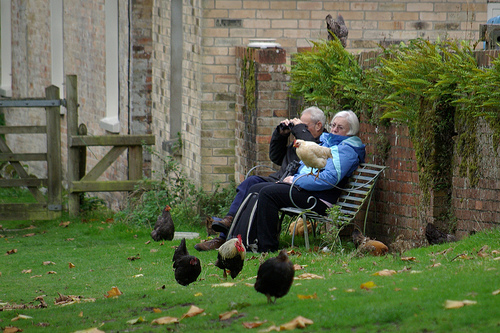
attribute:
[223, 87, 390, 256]
people — sitting, bench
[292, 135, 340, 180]
rooster — white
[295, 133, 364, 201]
coat — big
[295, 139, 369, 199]
coat — blue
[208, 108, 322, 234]
man — old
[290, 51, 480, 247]
wall — red, brick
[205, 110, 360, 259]
couple — old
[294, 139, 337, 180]
chicken — yellow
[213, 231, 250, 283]
rooster — black, white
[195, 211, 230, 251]
shoes — brown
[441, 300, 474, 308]
leaf — brown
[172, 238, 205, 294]
bird — large, black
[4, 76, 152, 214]
fence — wooden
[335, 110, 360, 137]
hair — gray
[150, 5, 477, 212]
building — brick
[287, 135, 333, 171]
bird — large, white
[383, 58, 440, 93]
leaves — green, tree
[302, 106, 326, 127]
hair — man's, short cut, gray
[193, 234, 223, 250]
shoe — brown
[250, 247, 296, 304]
chicken — fat, black, female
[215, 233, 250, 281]
chicken — female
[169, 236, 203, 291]
chicken — female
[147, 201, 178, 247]
chicken — female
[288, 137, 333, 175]
chicken — light brown, yellow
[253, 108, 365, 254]
woman — old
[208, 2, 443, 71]
wall — brick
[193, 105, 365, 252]
couple — older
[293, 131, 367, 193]
jacket — blue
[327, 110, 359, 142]
hair — gray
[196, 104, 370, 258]
people — old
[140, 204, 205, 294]
fowls — black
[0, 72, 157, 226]
fence — brown, wooden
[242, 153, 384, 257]
bench — green , metal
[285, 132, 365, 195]
jacket — light blue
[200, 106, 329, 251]
man — old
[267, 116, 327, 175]
jacket — black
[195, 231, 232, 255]
shoes — brown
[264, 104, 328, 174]
man — old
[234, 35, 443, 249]
wall — bricked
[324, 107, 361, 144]
hair — short, grey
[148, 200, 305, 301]
chickens — some, walking around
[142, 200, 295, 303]
chickens — some, looking for food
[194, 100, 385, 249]
relaxing — very, nicely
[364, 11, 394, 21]
brick — tan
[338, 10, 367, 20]
brick — tan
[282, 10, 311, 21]
brick — tan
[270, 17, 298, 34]
brick — tan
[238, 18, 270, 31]
brick — tan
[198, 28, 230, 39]
brick — tan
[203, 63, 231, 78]
brick — tan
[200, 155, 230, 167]
brick — tan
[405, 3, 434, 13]
brick — tan